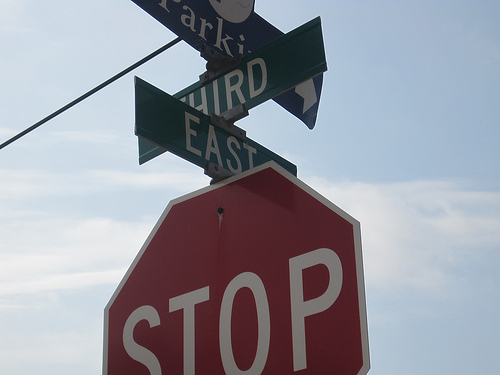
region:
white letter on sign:
[180, 3, 197, 28]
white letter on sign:
[196, 15, 213, 42]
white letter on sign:
[213, 17, 233, 56]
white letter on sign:
[186, 88, 208, 112]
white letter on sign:
[211, 76, 219, 116]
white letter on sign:
[224, 70, 244, 104]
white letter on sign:
[247, 56, 265, 98]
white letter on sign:
[183, 107, 205, 155]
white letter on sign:
[203, 124, 221, 164]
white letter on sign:
[224, 135, 242, 172]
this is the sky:
[371, 31, 496, 160]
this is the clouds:
[386, 177, 474, 247]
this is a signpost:
[91, 210, 380, 365]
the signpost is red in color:
[189, 183, 263, 218]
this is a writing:
[121, 270, 338, 369]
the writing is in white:
[155, 285, 331, 347]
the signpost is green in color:
[129, 86, 199, 149]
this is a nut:
[212, 200, 234, 227]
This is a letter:
[280, 233, 345, 372]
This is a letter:
[212, 259, 284, 374]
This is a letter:
[168, 277, 220, 373]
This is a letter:
[120, 298, 166, 373]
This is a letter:
[178, 101, 209, 170]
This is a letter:
[202, 116, 230, 181]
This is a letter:
[222, 127, 244, 177]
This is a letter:
[239, 133, 263, 205]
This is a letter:
[245, 50, 275, 105]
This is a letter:
[223, 64, 250, 118]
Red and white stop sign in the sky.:
[340, 322, 357, 339]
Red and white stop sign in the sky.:
[182, 239, 289, 264]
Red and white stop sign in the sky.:
[319, 331, 426, 348]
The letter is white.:
[282, 242, 349, 374]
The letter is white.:
[176, 106, 206, 156]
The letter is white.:
[202, 118, 227, 168]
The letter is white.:
[221, 128, 248, 177]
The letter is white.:
[208, 72, 222, 117]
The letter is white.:
[221, 62, 248, 114]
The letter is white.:
[243, 52, 272, 104]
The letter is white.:
[177, 0, 199, 36]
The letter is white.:
[196, 8, 214, 45]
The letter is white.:
[211, 9, 236, 61]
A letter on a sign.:
[116, 298, 162, 373]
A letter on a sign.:
[165, 285, 214, 371]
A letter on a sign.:
[214, 267, 274, 374]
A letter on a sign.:
[278, 240, 343, 365]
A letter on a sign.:
[183, 110, 200, 157]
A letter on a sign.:
[205, 122, 222, 168]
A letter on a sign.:
[223, 132, 243, 171]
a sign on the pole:
[119, 71, 269, 202]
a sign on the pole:
[143, 46, 321, 160]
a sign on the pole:
[147, 14, 274, 71]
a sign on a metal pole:
[105, 144, 338, 370]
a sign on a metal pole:
[110, 84, 265, 187]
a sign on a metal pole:
[186, 54, 327, 137]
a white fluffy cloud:
[385, 161, 455, 255]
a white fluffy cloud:
[388, 231, 423, 266]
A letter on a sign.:
[214, 267, 271, 369]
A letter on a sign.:
[286, 243, 348, 370]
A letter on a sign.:
[200, 119, 225, 165]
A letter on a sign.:
[221, 131, 238, 182]